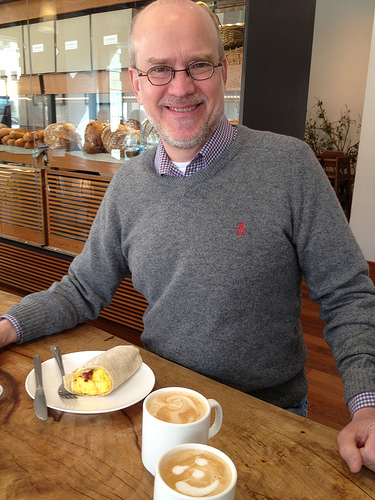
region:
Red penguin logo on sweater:
[234, 219, 248, 237]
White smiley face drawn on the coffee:
[171, 455, 222, 496]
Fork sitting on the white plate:
[49, 344, 77, 401]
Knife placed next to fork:
[31, 353, 50, 421]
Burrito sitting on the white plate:
[62, 344, 144, 395]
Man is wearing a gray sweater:
[0, 1, 373, 472]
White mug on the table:
[151, 443, 236, 499]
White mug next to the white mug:
[140, 385, 221, 473]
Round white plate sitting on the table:
[26, 351, 155, 414]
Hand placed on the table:
[338, 404, 374, 470]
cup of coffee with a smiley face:
[152, 443, 237, 499]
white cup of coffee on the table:
[141, 386, 223, 475]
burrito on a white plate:
[25, 344, 155, 413]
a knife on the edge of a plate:
[31, 352, 48, 420]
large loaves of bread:
[43, 119, 138, 155]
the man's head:
[127, 0, 228, 148]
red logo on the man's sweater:
[233, 220, 248, 237]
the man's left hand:
[335, 403, 374, 474]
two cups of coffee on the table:
[140, 385, 239, 499]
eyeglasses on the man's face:
[133, 58, 224, 86]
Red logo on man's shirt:
[234, 220, 247, 236]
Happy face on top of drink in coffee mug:
[155, 442, 238, 499]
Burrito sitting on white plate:
[24, 344, 156, 414]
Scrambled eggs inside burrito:
[69, 367, 111, 398]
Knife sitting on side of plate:
[32, 351, 48, 421]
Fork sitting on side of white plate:
[51, 343, 77, 399]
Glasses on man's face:
[132, 59, 224, 86]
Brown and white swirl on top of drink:
[147, 386, 208, 425]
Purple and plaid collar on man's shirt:
[152, 111, 237, 176]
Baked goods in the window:
[0, 119, 145, 158]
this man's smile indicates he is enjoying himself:
[125, 0, 233, 152]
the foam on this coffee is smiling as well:
[154, 440, 240, 499]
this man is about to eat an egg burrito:
[59, 337, 145, 399]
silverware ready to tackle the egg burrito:
[30, 339, 81, 423]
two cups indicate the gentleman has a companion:
[137, 382, 241, 498]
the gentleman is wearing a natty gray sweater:
[4, 119, 373, 410]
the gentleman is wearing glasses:
[134, 56, 225, 87]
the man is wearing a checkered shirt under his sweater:
[150, 109, 240, 180]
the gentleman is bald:
[125, 1, 233, 152]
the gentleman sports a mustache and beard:
[149, 92, 218, 150]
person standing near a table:
[1, 1, 373, 441]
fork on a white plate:
[44, 340, 80, 403]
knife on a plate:
[27, 347, 51, 425]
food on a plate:
[59, 340, 145, 401]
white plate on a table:
[24, 345, 157, 418]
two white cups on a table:
[136, 380, 241, 499]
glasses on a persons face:
[126, 54, 230, 90]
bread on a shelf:
[0, 117, 45, 150]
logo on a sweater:
[231, 218, 251, 242]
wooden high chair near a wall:
[312, 145, 355, 199]